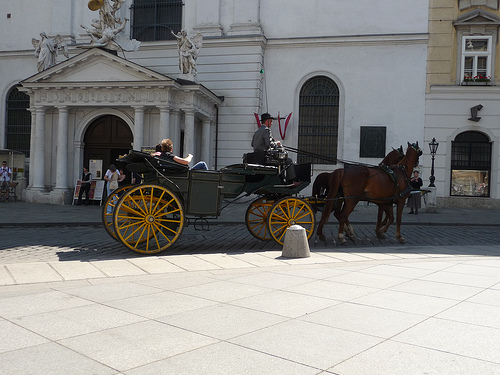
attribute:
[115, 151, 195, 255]
wheel — yellow, black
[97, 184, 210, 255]
wheels — yellow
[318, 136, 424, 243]
horse — here, brown, pulling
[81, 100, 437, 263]
chariot — here, black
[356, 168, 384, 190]
fur — brown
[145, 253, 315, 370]
ground — here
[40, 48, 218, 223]
building — here, tall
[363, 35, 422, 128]
wall — white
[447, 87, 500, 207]
door — here, wooden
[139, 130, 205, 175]
people — sitting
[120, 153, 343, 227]
carriage — pulled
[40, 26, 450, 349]
day — sunny, here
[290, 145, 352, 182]
reins — held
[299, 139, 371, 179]
ropes — held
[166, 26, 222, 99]
statue — white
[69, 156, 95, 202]
people — standing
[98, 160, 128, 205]
man — standing